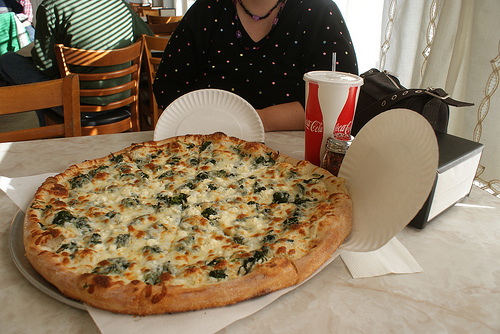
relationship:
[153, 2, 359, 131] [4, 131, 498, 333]
lady sitting at table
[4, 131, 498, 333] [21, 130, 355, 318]
table has pizza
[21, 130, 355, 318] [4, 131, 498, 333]
pizza sitting on table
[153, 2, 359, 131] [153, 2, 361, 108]
lady wearing shirt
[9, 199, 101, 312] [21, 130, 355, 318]
pan under pizza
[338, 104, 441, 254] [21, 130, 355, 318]
plate under pizza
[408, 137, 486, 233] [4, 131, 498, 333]
holder sits on table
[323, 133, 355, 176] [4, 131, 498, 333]
shaker on table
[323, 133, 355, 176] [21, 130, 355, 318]
shaker next to pizza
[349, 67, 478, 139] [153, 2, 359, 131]
purse next to lady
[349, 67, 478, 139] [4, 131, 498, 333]
purse on table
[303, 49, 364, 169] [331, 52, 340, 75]
cup has straw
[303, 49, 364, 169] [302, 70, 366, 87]
cup has lid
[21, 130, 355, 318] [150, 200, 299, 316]
pizza has slice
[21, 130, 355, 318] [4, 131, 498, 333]
pizza sits on table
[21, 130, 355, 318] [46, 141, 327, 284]
pizza has toppings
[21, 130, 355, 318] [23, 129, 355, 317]
pizza has crust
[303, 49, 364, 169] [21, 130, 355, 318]
cup next to pizza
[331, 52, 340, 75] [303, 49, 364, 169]
straw in cup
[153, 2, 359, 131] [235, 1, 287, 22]
lady has necklace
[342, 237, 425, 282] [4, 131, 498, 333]
napkin laying on table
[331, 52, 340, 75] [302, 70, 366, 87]
straw in lid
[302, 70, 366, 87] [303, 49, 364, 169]
lid on cup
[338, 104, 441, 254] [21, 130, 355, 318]
plate by a pizza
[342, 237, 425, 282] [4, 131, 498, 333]
napkin on table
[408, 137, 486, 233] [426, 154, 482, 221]
holder has napkins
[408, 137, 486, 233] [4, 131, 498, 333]
holder on table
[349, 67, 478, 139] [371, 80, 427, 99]
purse has zipper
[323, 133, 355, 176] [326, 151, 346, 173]
shaker has pepper